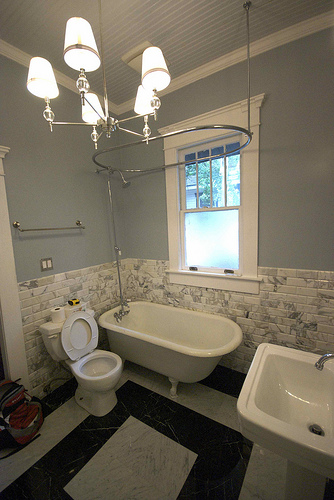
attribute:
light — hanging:
[27, 51, 59, 105]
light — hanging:
[67, 23, 99, 73]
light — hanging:
[83, 90, 102, 123]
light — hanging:
[135, 90, 154, 117]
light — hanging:
[140, 48, 168, 90]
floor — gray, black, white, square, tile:
[1, 363, 326, 499]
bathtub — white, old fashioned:
[99, 297, 241, 396]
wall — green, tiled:
[114, 30, 331, 370]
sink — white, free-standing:
[236, 343, 333, 499]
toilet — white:
[41, 310, 121, 416]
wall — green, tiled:
[1, 51, 117, 384]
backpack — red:
[3, 386, 45, 448]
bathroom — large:
[3, 4, 329, 498]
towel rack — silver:
[14, 219, 87, 234]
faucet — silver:
[314, 347, 332, 370]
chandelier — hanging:
[29, 19, 169, 147]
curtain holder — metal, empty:
[93, 123, 251, 182]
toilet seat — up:
[63, 312, 99, 359]